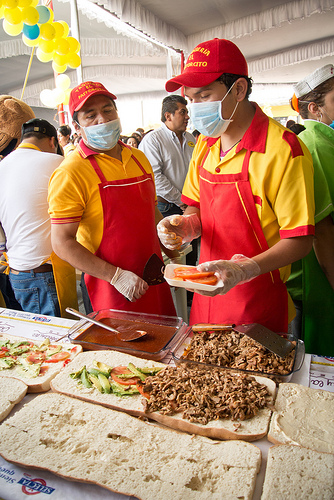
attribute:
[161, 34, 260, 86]
hat — red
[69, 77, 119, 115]
hat — red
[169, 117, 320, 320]
shirt — red, yellow, green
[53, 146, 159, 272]
shirt — red, yellow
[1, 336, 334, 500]
bread — large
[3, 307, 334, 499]
table — here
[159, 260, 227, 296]
tray — white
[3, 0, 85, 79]
balloons — blue, yellow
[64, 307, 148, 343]
spoon — grey, big, silver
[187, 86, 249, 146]
mask — blue, light blue, white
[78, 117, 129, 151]
mask — blue, white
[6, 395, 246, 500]
slice — empty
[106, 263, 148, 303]
glove — here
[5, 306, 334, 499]
cloth — here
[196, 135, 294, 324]
apron — red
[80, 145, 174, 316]
apron — red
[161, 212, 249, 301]
gloves — latex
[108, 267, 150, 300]
gloves — latex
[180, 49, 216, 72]
lettering — yellow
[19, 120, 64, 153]
hat — black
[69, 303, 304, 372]
dishes — glass